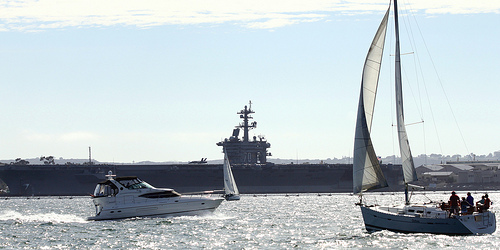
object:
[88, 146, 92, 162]
crane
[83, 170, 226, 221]
ship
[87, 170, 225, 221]
boat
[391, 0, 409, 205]
mast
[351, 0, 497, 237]
sailboat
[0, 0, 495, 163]
sky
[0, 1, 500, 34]
clouds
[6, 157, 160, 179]
hill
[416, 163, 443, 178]
building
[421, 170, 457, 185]
building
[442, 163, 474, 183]
building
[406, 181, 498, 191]
shore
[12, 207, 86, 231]
wake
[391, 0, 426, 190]
rope ladder